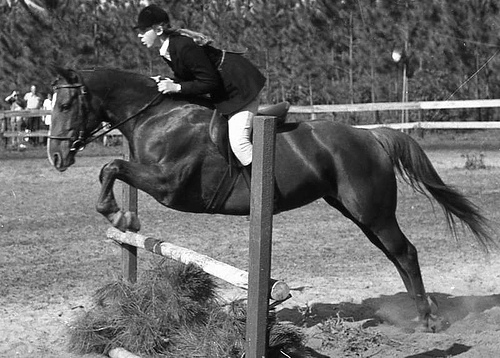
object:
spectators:
[4, 86, 60, 116]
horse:
[43, 61, 500, 336]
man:
[22, 83, 45, 143]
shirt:
[24, 92, 42, 109]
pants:
[228, 98, 258, 167]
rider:
[136, 6, 265, 178]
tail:
[385, 127, 500, 262]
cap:
[131, 5, 172, 30]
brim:
[131, 23, 146, 30]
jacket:
[159, 29, 268, 118]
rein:
[68, 67, 175, 150]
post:
[245, 116, 276, 357]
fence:
[260, 99, 500, 131]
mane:
[68, 69, 161, 113]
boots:
[240, 161, 257, 222]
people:
[3, 84, 56, 144]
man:
[5, 90, 26, 149]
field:
[0, 142, 500, 358]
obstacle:
[92, 114, 279, 358]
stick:
[105, 222, 291, 301]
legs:
[94, 156, 434, 332]